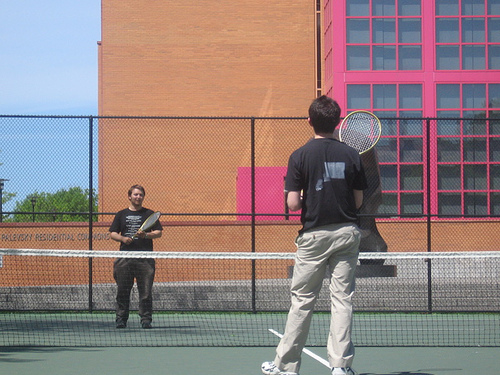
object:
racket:
[338, 108, 383, 156]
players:
[107, 94, 366, 374]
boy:
[259, 95, 367, 374]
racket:
[123, 210, 162, 245]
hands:
[123, 230, 146, 244]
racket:
[131, 110, 382, 241]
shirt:
[284, 137, 371, 233]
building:
[97, 0, 500, 222]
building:
[236, 164, 319, 220]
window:
[346, 0, 421, 71]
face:
[131, 188, 145, 205]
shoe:
[140, 317, 154, 330]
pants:
[274, 225, 362, 362]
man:
[108, 183, 163, 329]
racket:
[131, 211, 161, 240]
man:
[261, 95, 367, 374]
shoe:
[259, 359, 302, 375]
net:
[0, 256, 500, 346]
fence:
[0, 253, 500, 347]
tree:
[11, 186, 99, 225]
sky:
[26, 23, 83, 100]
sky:
[0, 0, 98, 190]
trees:
[0, 183, 100, 225]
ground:
[0, 309, 497, 375]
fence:
[0, 115, 497, 310]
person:
[259, 95, 365, 374]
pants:
[274, 222, 361, 367]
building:
[315, 0, 498, 223]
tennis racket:
[338, 109, 383, 155]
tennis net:
[0, 248, 497, 346]